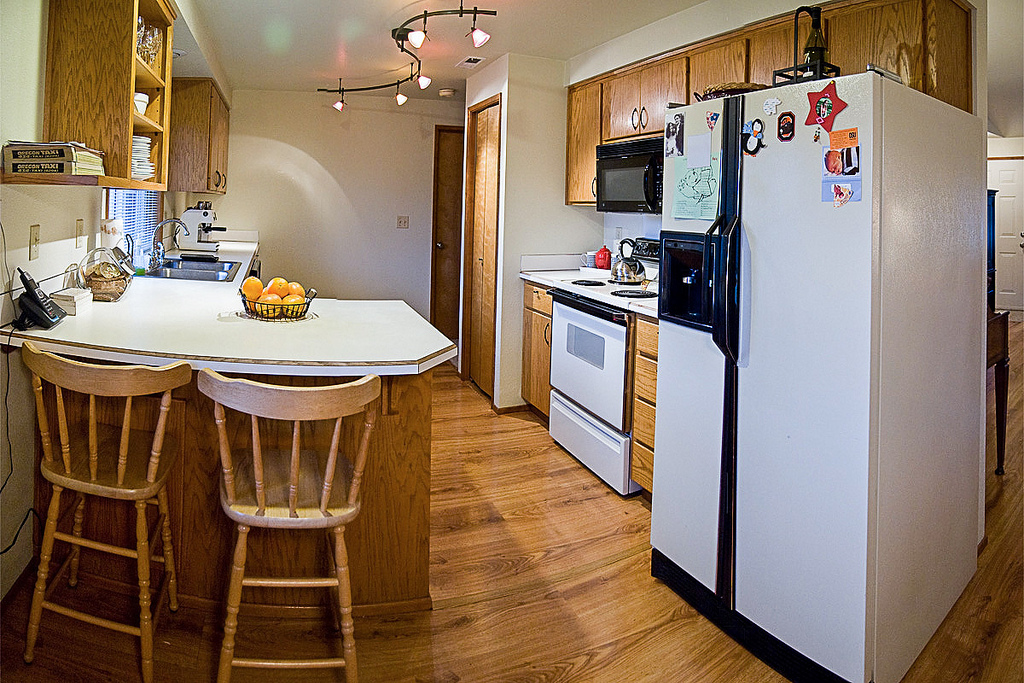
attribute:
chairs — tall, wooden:
[2, 327, 386, 667]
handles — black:
[683, 195, 757, 366]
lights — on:
[302, 2, 498, 116]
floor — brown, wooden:
[1, 308, 1013, 669]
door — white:
[529, 283, 627, 435]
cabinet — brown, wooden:
[550, 61, 611, 211]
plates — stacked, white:
[114, 122, 166, 189]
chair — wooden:
[245, 286, 420, 599]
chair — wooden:
[24, 364, 260, 674]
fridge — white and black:
[548, 68, 900, 672]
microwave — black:
[544, 125, 681, 230]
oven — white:
[506, 266, 621, 462]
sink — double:
[139, 245, 243, 282]